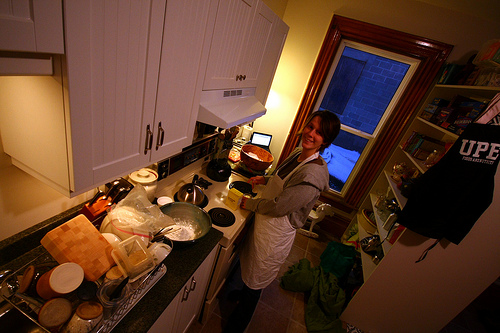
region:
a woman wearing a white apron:
[224, 112, 339, 332]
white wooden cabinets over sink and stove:
[0, 2, 290, 200]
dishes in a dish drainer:
[2, 184, 171, 331]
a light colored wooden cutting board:
[39, 214, 117, 281]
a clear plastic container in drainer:
[110, 233, 155, 284]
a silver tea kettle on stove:
[176, 174, 205, 204]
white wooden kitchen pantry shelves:
[341, 84, 498, 331]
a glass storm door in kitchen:
[298, 39, 420, 199]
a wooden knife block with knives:
[82, 180, 127, 227]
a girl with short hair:
[225, 110, 340, 331]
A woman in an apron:
[220, 109, 342, 331]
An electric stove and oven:
[147, 153, 264, 325]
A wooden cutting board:
[39, 212, 125, 283]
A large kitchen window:
[291, 35, 421, 200]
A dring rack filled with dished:
[3, 213, 168, 332]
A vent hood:
[197, 87, 265, 127]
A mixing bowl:
[157, 199, 213, 247]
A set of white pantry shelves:
[339, 80, 499, 332]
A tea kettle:
[176, 170, 207, 207]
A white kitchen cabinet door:
[64, 0, 167, 193]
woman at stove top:
[245, 103, 336, 331]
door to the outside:
[307, 35, 382, 207]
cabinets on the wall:
[71, 7, 188, 160]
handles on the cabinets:
[128, 108, 166, 153]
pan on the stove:
[231, 180, 260, 200]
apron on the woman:
[246, 150, 293, 290]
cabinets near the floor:
[168, 259, 212, 328]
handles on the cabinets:
[180, 278, 205, 304]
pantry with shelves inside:
[354, 81, 487, 308]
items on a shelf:
[425, 100, 470, 125]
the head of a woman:
[283, 103, 374, 164]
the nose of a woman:
[298, 125, 324, 146]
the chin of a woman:
[291, 131, 315, 167]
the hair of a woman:
[289, 109, 357, 161]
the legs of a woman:
[216, 234, 301, 331]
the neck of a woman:
[298, 137, 339, 203]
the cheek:
[285, 115, 345, 171]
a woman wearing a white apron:
[230, 108, 348, 297]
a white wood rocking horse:
[297, 200, 337, 244]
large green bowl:
[148, 199, 217, 254]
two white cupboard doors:
[62, 0, 214, 202]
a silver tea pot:
[174, 168, 212, 208]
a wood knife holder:
[80, 177, 128, 219]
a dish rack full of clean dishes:
[6, 214, 173, 326]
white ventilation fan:
[197, 83, 270, 130]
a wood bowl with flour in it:
[237, 141, 277, 177]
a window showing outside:
[287, 34, 425, 202]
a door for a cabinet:
[2, 0, 61, 55]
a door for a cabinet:
[71, 0, 152, 190]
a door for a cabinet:
[158, 2, 194, 155]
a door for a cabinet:
[198, 1, 249, 87]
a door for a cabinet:
[235, 5, 275, 87]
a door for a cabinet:
[251, 8, 286, 105]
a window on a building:
[313, 37, 409, 137]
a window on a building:
[308, 117, 365, 197]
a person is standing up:
[229, 107, 338, 320]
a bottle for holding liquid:
[381, 210, 398, 233]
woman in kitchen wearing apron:
[230, 105, 340, 299]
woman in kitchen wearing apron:
[224, 102, 346, 296]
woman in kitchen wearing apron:
[224, 113, 341, 295]